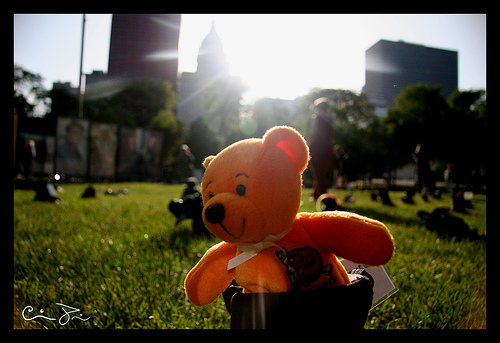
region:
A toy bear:
[219, 140, 321, 330]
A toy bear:
[244, 191, 299, 307]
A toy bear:
[211, 159, 291, 270]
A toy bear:
[179, 189, 254, 310]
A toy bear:
[189, 79, 326, 294]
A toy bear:
[219, 189, 279, 294]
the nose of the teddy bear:
[202, 196, 229, 226]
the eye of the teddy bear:
[232, 179, 250, 201]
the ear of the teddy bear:
[263, 118, 313, 178]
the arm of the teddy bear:
[303, 202, 398, 274]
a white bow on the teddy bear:
[223, 218, 298, 277]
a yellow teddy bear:
[177, 121, 397, 313]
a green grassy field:
[13, 175, 485, 331]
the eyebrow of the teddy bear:
[226, 165, 253, 182]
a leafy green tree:
[381, 72, 452, 172]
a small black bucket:
[218, 260, 375, 329]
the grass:
[78, 254, 100, 284]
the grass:
[457, 282, 471, 301]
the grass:
[395, 289, 428, 325]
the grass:
[65, 240, 99, 267]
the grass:
[66, 226, 132, 303]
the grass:
[88, 258, 169, 308]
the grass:
[37, 199, 159, 327]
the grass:
[87, 265, 185, 335]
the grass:
[97, 212, 194, 297]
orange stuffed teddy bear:
[187, 129, 406, 309]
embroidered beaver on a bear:
[271, 237, 348, 293]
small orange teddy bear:
[179, 134, 392, 341]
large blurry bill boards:
[42, 98, 187, 193]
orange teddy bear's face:
[193, 128, 320, 246]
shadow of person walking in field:
[407, 195, 492, 260]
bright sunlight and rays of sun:
[157, 73, 368, 166]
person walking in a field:
[307, 89, 342, 203]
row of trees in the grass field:
[341, 84, 498, 220]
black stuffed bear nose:
[204, 197, 232, 235]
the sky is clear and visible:
[224, 61, 375, 123]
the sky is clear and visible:
[168, 19, 326, 131]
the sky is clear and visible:
[62, 21, 322, 149]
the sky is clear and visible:
[41, 3, 178, 120]